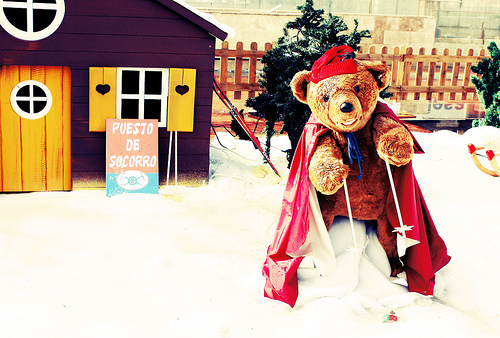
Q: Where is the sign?
A: Against the house.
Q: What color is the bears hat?
A: Red.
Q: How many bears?
A: One.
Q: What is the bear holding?
A: Poles.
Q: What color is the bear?
A: Brown.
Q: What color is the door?
A: Yellow.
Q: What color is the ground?
A: White.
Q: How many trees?
A: Two.